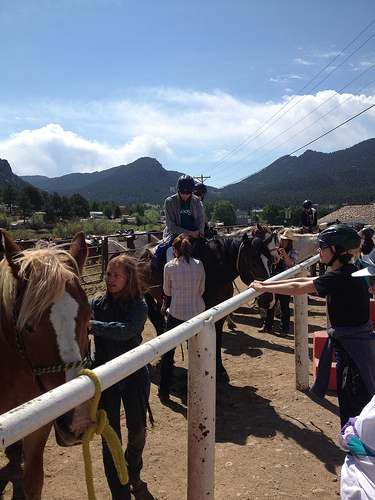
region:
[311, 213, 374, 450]
This is a person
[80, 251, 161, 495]
This is a person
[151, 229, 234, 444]
This is a person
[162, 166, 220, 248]
This is a person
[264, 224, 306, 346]
This is a person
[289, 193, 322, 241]
This is a person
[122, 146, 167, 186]
This is a hill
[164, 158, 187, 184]
This is a hill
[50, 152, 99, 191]
This is a hill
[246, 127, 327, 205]
This is a hill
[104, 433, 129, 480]
rope on the railing.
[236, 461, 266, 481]
dirt on the ground.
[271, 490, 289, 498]
rocks in the dirt.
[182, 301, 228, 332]
white railing near horse.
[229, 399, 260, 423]
shadow on the ground.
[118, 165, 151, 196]
bluffs in the distance.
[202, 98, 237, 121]
clouds in the sky.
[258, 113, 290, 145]
wires above the crowd.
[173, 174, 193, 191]
helmet on rider's head.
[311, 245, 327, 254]
glasses on person's face.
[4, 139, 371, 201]
The hills in the background.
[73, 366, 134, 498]
The yellow rope on the pole.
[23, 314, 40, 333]
The eye of the brown horse.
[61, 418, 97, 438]
The nose of the brown horse.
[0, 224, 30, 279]
The left ear of the brown horse.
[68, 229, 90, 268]
The right ear of the brown horse.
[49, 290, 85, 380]
The white marking on the brown horse's head.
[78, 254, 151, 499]
The girl standing next to the brown horse.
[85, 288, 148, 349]
The shirt the girl is wearing standing next to the brown horse.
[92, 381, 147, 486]
The pants the girl standing next to the brown horse is wearing.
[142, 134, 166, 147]
part of a cloud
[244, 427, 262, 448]
part of a shade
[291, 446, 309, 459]
part of a floor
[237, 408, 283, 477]
part of a shade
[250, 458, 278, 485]
part of a ground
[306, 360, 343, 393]
part of a cloth